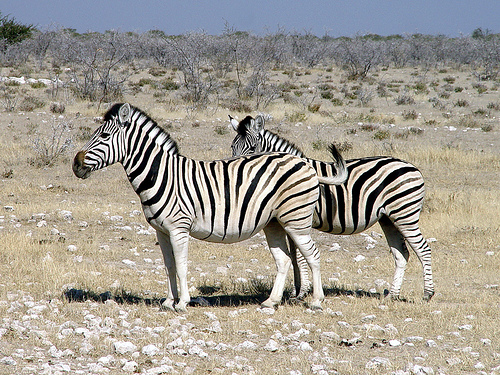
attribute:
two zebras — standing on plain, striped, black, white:
[73, 103, 436, 312]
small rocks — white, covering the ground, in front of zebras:
[6, 201, 498, 372]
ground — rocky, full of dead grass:
[3, 24, 496, 374]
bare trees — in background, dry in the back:
[19, 34, 494, 104]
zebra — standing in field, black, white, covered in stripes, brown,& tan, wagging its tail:
[65, 101, 351, 315]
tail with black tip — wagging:
[316, 142, 349, 188]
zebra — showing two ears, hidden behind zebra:
[226, 113, 440, 302]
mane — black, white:
[103, 102, 177, 159]